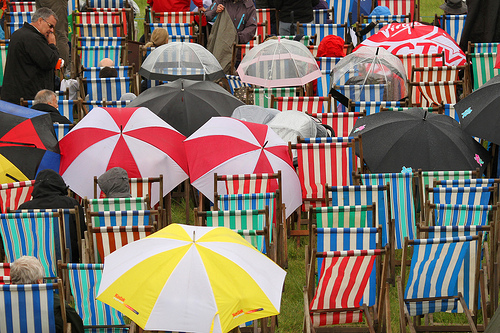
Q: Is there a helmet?
A: No, there are no helmets.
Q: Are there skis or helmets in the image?
A: No, there are no helmets or skis.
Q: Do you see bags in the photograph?
A: No, there are no bags.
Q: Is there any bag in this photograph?
A: No, there are no bags.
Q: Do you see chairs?
A: Yes, there is a chair.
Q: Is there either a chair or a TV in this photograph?
A: Yes, there is a chair.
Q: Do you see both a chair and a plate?
A: No, there is a chair but no plates.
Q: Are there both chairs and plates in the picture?
A: No, there is a chair but no plates.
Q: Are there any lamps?
A: No, there are no lamps.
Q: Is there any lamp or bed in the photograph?
A: No, there are no lamps or beds.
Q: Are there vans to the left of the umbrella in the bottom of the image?
A: No, there is a chair to the left of the umbrella.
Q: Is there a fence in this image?
A: No, there are no fences.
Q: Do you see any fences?
A: No, there are no fences.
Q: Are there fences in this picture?
A: No, there are no fences.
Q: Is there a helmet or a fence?
A: No, there are no fences or helmets.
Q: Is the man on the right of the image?
A: No, the man is on the left of the image.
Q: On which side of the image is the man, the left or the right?
A: The man is on the left of the image.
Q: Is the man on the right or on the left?
A: The man is on the left of the image.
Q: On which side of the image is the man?
A: The man is on the left of the image.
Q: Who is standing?
A: The man is standing.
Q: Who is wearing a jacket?
A: The man is wearing a jacket.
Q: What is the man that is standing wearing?
A: The man is wearing a jacket.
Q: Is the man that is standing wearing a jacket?
A: Yes, the man is wearing a jacket.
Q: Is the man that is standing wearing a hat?
A: No, the man is wearing a jacket.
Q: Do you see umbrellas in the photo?
A: Yes, there is an umbrella.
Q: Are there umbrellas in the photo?
A: Yes, there is an umbrella.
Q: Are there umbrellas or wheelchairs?
A: Yes, there is an umbrella.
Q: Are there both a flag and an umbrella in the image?
A: No, there is an umbrella but no flags.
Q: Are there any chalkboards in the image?
A: No, there are no chalkboards.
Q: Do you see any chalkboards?
A: No, there are no chalkboards.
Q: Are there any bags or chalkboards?
A: No, there are no chalkboards or bags.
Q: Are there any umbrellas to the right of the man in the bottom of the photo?
A: Yes, there is an umbrella to the right of the man.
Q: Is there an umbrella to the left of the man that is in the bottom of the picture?
A: No, the umbrella is to the right of the man.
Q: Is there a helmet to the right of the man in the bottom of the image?
A: No, there is an umbrella to the right of the man.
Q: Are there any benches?
A: No, there are no benches.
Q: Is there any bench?
A: No, there are no benches.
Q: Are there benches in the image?
A: No, there are no benches.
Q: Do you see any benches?
A: No, there are no benches.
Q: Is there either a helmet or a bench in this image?
A: No, there are no benches or helmets.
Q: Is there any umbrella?
A: Yes, there is an umbrella.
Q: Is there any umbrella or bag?
A: Yes, there is an umbrella.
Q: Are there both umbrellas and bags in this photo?
A: No, there is an umbrella but no bags.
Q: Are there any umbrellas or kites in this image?
A: Yes, there is an umbrella.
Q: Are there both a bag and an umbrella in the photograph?
A: No, there is an umbrella but no bags.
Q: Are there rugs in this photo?
A: No, there are no rugs.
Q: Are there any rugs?
A: No, there are no rugs.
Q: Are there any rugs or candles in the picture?
A: No, there are no rugs or candles.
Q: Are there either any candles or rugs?
A: No, there are no rugs or candles.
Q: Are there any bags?
A: No, there are no bags.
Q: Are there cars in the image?
A: No, there are no cars.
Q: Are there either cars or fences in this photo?
A: No, there are no cars or fences.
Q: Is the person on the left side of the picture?
A: Yes, the person is on the left of the image.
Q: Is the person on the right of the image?
A: No, the person is on the left of the image.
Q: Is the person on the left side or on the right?
A: The person is on the left of the image.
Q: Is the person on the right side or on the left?
A: The person is on the left of the image.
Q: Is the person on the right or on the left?
A: The person is on the left of the image.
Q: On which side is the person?
A: The person is on the left of the image.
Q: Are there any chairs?
A: Yes, there is a chair.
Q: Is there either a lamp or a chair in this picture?
A: Yes, there is a chair.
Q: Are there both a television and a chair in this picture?
A: No, there is a chair but no televisions.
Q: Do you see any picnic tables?
A: No, there are no picnic tables.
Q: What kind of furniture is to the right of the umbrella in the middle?
A: The piece of furniture is a chair.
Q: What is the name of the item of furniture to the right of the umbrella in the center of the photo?
A: The piece of furniture is a chair.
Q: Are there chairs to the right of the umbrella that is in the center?
A: Yes, there is a chair to the right of the umbrella.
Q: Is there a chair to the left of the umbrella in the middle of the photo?
A: No, the chair is to the right of the umbrella.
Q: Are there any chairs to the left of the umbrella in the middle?
A: No, the chair is to the right of the umbrella.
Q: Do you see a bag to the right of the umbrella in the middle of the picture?
A: No, there is a chair to the right of the umbrella.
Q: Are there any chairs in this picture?
A: Yes, there is a chair.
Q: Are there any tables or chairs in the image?
A: Yes, there is a chair.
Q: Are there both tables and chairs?
A: No, there is a chair but no tables.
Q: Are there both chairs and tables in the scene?
A: No, there is a chair but no tables.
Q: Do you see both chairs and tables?
A: No, there is a chair but no tables.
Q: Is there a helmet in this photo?
A: No, there are no helmets.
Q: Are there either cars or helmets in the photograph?
A: No, there are no helmets or cars.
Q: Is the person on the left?
A: Yes, the person is on the left of the image.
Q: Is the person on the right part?
A: No, the person is on the left of the image.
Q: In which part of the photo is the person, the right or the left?
A: The person is on the left of the image.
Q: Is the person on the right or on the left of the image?
A: The person is on the left of the image.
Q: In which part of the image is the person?
A: The person is on the left of the image.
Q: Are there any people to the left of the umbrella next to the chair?
A: Yes, there is a person to the left of the umbrella.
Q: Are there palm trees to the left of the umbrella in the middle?
A: No, there is a person to the left of the umbrella.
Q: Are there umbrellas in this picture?
A: Yes, there is an umbrella.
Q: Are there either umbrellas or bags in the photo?
A: Yes, there is an umbrella.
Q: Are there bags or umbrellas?
A: Yes, there is an umbrella.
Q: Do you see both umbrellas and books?
A: No, there is an umbrella but no books.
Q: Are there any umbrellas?
A: Yes, there is an umbrella.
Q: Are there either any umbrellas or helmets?
A: Yes, there is an umbrella.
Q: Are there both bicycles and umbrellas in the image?
A: No, there is an umbrella but no bicycles.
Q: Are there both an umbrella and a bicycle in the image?
A: No, there is an umbrella but no bicycles.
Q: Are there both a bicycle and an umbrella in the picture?
A: No, there is an umbrella but no bicycles.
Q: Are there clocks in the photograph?
A: No, there are no clocks.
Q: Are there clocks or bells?
A: No, there are no clocks or bells.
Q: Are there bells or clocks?
A: No, there are no clocks or bells.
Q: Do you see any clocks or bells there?
A: No, there are no clocks or bells.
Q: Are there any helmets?
A: No, there are no helmets.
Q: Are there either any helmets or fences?
A: No, there are no helmets or fences.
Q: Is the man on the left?
A: Yes, the man is on the left of the image.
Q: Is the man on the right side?
A: No, the man is on the left of the image.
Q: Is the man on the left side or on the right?
A: The man is on the left of the image.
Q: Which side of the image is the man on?
A: The man is on the left of the image.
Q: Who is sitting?
A: The man is sitting.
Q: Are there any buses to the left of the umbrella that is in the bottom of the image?
A: No, there is a man to the left of the umbrella.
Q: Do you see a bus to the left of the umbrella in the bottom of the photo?
A: No, there is a man to the left of the umbrella.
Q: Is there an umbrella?
A: Yes, there is an umbrella.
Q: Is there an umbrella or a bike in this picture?
A: Yes, there is an umbrella.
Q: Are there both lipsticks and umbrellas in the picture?
A: No, there is an umbrella but no lipsticks.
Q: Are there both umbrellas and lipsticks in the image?
A: No, there is an umbrella but no lipsticks.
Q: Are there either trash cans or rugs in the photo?
A: No, there are no rugs or trash cans.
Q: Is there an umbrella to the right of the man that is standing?
A: Yes, there is an umbrella to the right of the man.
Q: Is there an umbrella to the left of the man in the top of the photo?
A: No, the umbrella is to the right of the man.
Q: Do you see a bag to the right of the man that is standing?
A: No, there is an umbrella to the right of the man.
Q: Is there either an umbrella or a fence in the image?
A: Yes, there is an umbrella.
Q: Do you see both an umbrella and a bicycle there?
A: No, there is an umbrella but no bicycles.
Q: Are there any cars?
A: No, there are no cars.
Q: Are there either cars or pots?
A: No, there are no cars or pots.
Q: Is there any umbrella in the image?
A: Yes, there is an umbrella.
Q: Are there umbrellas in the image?
A: Yes, there is an umbrella.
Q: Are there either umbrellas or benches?
A: Yes, there is an umbrella.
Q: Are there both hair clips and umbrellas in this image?
A: No, there is an umbrella but no hair clips.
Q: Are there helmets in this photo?
A: No, there are no helmets.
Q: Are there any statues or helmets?
A: No, there are no helmets or statues.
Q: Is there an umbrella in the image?
A: Yes, there is an umbrella.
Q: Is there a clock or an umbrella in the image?
A: Yes, there is an umbrella.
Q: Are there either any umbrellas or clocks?
A: Yes, there is an umbrella.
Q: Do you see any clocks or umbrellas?
A: Yes, there is an umbrella.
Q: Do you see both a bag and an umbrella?
A: No, there is an umbrella but no bags.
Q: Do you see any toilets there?
A: No, there are no toilets.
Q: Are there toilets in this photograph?
A: No, there are no toilets.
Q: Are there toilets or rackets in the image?
A: No, there are no toilets or rackets.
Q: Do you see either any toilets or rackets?
A: No, there are no toilets or rackets.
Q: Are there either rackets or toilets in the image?
A: No, there are no toilets or rackets.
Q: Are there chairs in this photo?
A: Yes, there is a chair.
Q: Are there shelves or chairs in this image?
A: Yes, there is a chair.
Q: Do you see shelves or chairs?
A: Yes, there is a chair.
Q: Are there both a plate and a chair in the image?
A: No, there is a chair but no plates.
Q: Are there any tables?
A: No, there are no tables.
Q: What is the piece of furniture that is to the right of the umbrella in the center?
A: The piece of furniture is a chair.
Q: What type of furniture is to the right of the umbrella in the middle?
A: The piece of furniture is a chair.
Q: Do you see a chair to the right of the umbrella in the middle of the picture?
A: Yes, there is a chair to the right of the umbrella.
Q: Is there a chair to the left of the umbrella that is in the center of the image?
A: No, the chair is to the right of the umbrella.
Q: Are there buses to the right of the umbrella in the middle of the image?
A: No, there is a chair to the right of the umbrella.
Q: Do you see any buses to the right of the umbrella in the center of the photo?
A: No, there is a chair to the right of the umbrella.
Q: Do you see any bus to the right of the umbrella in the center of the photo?
A: No, there is a chair to the right of the umbrella.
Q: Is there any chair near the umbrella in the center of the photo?
A: Yes, there is a chair near the umbrella.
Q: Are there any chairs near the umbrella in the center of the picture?
A: Yes, there is a chair near the umbrella.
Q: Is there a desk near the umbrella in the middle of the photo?
A: No, there is a chair near the umbrella.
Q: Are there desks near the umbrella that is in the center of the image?
A: No, there is a chair near the umbrella.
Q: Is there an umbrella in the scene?
A: Yes, there is an umbrella.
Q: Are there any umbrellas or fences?
A: Yes, there is an umbrella.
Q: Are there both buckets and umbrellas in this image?
A: No, there is an umbrella but no buckets.